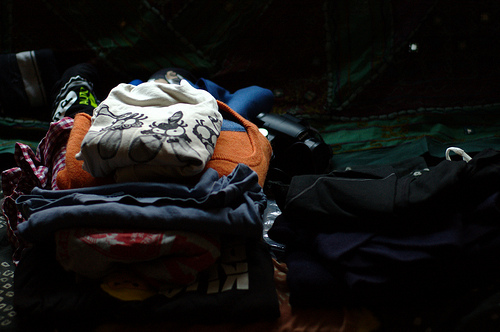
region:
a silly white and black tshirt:
[77, 75, 226, 181]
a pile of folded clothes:
[16, 71, 281, 330]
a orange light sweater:
[57, 103, 269, 185]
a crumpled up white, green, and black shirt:
[49, 65, 97, 115]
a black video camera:
[255, 106, 329, 164]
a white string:
[441, 145, 471, 163]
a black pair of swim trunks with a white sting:
[281, 147, 498, 221]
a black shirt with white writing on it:
[11, 248, 279, 322]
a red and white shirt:
[62, 230, 222, 275]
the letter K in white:
[220, 262, 252, 290]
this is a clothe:
[97, 88, 202, 165]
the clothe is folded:
[98, 89, 205, 163]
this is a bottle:
[280, 113, 316, 157]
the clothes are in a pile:
[38, 158, 254, 313]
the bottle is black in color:
[273, 114, 310, 155]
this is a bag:
[342, 27, 448, 91]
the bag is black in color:
[345, 8, 459, 95]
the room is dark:
[188, 8, 268, 52]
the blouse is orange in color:
[225, 130, 259, 160]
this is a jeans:
[166, 200, 188, 216]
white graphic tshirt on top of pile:
[113, 76, 223, 176]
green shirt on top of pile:
[337, 111, 412, 148]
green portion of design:
[73, 79, 104, 110]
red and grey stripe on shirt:
[28, 146, 56, 177]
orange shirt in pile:
[234, 120, 260, 171]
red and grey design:
[101, 224, 146, 245]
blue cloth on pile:
[221, 80, 250, 115]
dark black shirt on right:
[337, 171, 434, 230]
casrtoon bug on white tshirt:
[113, 111, 250, 183]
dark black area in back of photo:
[188, 5, 263, 47]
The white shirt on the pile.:
[88, 84, 215, 164]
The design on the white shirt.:
[99, 100, 211, 167]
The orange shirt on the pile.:
[67, 107, 264, 185]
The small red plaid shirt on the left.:
[5, 127, 71, 201]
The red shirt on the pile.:
[61, 230, 214, 278]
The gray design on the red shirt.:
[71, 218, 182, 255]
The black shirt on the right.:
[297, 155, 495, 220]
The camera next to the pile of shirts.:
[255, 100, 342, 176]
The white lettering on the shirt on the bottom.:
[207, 267, 258, 287]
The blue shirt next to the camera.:
[182, 78, 277, 107]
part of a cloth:
[148, 80, 168, 108]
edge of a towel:
[196, 207, 238, 257]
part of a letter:
[233, 265, 246, 282]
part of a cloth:
[207, 174, 250, 230]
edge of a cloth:
[196, 185, 226, 220]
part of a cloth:
[319, 262, 336, 314]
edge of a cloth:
[166, 150, 191, 182]